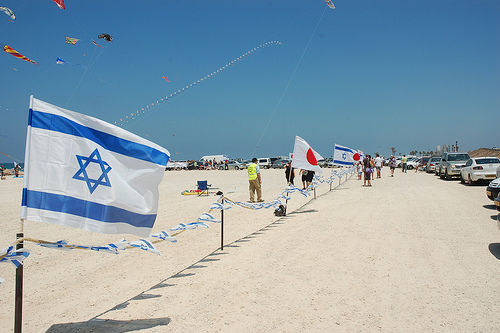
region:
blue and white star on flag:
[59, 138, 129, 192]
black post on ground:
[213, 189, 232, 249]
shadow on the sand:
[89, 287, 196, 319]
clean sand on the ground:
[292, 223, 399, 308]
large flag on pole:
[9, 80, 194, 246]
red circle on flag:
[301, 144, 327, 163]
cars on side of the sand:
[419, 144, 485, 188]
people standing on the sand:
[360, 149, 382, 188]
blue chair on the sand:
[185, 166, 217, 198]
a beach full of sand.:
[340, 237, 421, 325]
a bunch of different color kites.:
[0, 0, 117, 68]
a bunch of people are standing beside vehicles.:
[186, 156, 246, 171]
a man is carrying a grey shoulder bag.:
[361, 159, 373, 174]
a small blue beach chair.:
[191, 177, 213, 195]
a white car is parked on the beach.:
[459, 153, 499, 184]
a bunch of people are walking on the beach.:
[350, 148, 411, 188]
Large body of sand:
[326, 221, 421, 311]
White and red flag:
[289, 128, 325, 178]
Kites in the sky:
[9, 11, 120, 66]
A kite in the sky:
[60, 32, 80, 44]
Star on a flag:
[67, 142, 116, 198]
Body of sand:
[338, 217, 443, 291]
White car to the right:
[457, 154, 497, 185]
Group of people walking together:
[364, 152, 386, 177]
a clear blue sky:
[445, 22, 482, 72]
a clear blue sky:
[362, 9, 420, 57]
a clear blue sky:
[375, 43, 400, 77]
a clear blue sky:
[417, 78, 458, 98]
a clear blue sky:
[353, 86, 390, 118]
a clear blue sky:
[300, 75, 340, 109]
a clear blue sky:
[239, 62, 283, 97]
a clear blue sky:
[179, 36, 210, 58]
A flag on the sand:
[15, 94, 172, 332]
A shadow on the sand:
[48, 317, 171, 331]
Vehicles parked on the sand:
[219, 159, 499, 208]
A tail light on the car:
[468, 164, 485, 172]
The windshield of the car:
[448, 153, 468, 162]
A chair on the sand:
[196, 179, 210, 195]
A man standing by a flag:
[247, 162, 263, 200]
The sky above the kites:
[0, 1, 497, 163]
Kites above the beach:
[1, 1, 113, 68]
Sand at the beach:
[0, 170, 497, 332]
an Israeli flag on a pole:
[16, 94, 168, 332]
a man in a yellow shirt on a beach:
[245, 158, 264, 206]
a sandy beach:
[0, 168, 499, 330]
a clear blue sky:
[0, 0, 496, 163]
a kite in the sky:
[95, 32, 111, 44]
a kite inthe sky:
[2, 44, 34, 64]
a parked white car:
[460, 158, 496, 189]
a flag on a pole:
[285, 134, 320, 221]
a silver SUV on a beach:
[440, 150, 469, 180]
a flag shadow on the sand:
[49, 314, 176, 332]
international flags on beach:
[9, 10, 433, 320]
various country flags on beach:
[16, 48, 419, 315]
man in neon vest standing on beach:
[228, 139, 273, 213]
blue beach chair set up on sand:
[181, 170, 216, 200]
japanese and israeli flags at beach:
[246, 108, 400, 234]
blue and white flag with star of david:
[10, 80, 210, 272]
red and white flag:
[253, 119, 349, 226]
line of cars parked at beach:
[393, 132, 498, 217]